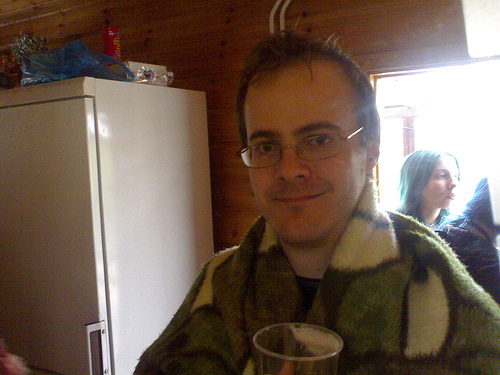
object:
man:
[130, 29, 499, 375]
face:
[242, 58, 368, 244]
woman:
[392, 151, 460, 238]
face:
[426, 156, 457, 209]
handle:
[79, 317, 108, 375]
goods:
[99, 26, 122, 60]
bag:
[10, 31, 135, 88]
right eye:
[436, 169, 448, 178]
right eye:
[248, 145, 278, 158]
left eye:
[301, 130, 337, 149]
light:
[361, 64, 499, 217]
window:
[367, 52, 500, 238]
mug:
[251, 319, 343, 374]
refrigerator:
[0, 75, 217, 375]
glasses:
[237, 120, 362, 169]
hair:
[233, 26, 379, 139]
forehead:
[243, 59, 361, 123]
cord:
[262, 2, 284, 33]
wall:
[0, 2, 468, 252]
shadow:
[181, 81, 217, 278]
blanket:
[128, 178, 497, 374]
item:
[113, 57, 177, 85]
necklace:
[426, 221, 438, 231]